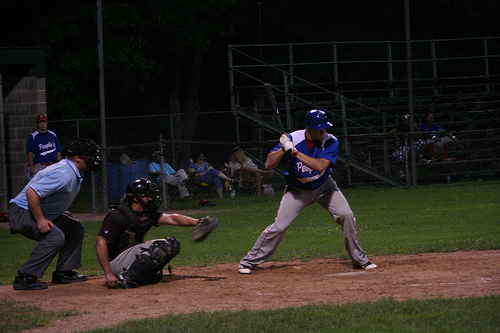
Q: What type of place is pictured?
A: It is a field.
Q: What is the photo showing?
A: It is showing a field.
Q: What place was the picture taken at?
A: It was taken at the field.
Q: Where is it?
A: This is at the field.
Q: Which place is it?
A: It is a field.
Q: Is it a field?
A: Yes, it is a field.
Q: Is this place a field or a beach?
A: It is a field.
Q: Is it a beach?
A: No, it is a field.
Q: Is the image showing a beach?
A: No, the picture is showing a field.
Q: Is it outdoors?
A: Yes, it is outdoors.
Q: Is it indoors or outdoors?
A: It is outdoors.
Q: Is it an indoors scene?
A: No, it is outdoors.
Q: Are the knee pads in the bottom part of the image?
A: Yes, the knee pads are in the bottom of the image.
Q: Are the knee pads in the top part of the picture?
A: No, the knee pads are in the bottom of the image.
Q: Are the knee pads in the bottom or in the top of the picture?
A: The knee pads are in the bottom of the image.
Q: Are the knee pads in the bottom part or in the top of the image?
A: The knee pads are in the bottom of the image.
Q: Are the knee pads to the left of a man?
A: No, the knee pads are to the right of a man.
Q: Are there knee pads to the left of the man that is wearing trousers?
A: Yes, there are knee pads to the left of the man.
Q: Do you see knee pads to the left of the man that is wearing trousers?
A: Yes, there are knee pads to the left of the man.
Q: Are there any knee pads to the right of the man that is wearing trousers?
A: No, the knee pads are to the left of the man.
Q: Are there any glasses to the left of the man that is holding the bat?
A: No, there are knee pads to the left of the man.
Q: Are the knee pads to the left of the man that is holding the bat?
A: Yes, the knee pads are to the left of the man.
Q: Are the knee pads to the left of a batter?
A: No, the knee pads are to the left of the man.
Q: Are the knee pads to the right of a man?
A: No, the knee pads are to the left of a man.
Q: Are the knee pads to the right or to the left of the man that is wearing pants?
A: The knee pads are to the left of the man.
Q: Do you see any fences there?
A: Yes, there is a fence.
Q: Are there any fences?
A: Yes, there is a fence.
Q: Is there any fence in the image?
A: Yes, there is a fence.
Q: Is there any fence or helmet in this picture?
A: Yes, there is a fence.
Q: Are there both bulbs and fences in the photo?
A: No, there is a fence but no light bulbs.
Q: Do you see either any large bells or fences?
A: Yes, there is a large fence.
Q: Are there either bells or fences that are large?
A: Yes, the fence is large.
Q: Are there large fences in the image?
A: Yes, there is a large fence.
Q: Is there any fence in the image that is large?
A: Yes, there is a fence that is large.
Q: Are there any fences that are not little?
A: Yes, there is a large fence.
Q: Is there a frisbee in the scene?
A: No, there are no frisbees.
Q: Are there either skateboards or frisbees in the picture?
A: No, there are no frisbees or skateboards.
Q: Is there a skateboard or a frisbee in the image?
A: No, there are no frisbees or skateboards.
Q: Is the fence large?
A: Yes, the fence is large.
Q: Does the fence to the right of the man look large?
A: Yes, the fence is large.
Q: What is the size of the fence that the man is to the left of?
A: The fence is large.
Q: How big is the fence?
A: The fence is large.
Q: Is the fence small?
A: No, the fence is large.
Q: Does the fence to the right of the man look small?
A: No, the fence is large.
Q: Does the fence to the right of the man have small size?
A: No, the fence is large.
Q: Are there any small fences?
A: No, there is a fence but it is large.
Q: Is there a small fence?
A: No, there is a fence but it is large.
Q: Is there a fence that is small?
A: No, there is a fence but it is large.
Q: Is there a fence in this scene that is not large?
A: No, there is a fence but it is large.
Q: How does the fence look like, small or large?
A: The fence is large.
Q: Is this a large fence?
A: Yes, this is a large fence.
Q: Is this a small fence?
A: No, this is a large fence.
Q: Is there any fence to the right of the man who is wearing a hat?
A: Yes, there is a fence to the right of the man.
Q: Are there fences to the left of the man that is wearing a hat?
A: No, the fence is to the right of the man.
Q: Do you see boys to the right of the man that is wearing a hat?
A: No, there is a fence to the right of the man.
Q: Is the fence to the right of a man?
A: Yes, the fence is to the right of a man.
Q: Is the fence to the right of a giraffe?
A: No, the fence is to the right of a man.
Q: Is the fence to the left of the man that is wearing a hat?
A: No, the fence is to the right of the man.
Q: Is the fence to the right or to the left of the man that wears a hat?
A: The fence is to the right of the man.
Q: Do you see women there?
A: No, there are no women.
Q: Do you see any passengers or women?
A: No, there are no women or passengers.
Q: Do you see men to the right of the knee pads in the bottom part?
A: Yes, there is a man to the right of the knee pads.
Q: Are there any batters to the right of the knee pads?
A: No, there is a man to the right of the knee pads.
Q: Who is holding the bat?
A: The man is holding the bat.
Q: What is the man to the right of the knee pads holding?
A: The man is holding the bat.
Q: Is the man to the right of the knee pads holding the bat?
A: Yes, the man is holding the bat.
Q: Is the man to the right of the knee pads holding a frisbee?
A: No, the man is holding the bat.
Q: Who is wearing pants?
A: The man is wearing pants.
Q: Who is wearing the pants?
A: The man is wearing pants.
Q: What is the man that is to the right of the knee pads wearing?
A: The man is wearing trousers.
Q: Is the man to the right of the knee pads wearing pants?
A: Yes, the man is wearing pants.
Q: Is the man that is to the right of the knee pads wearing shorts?
A: No, the man is wearing pants.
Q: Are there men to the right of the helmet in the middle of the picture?
A: Yes, there is a man to the right of the helmet.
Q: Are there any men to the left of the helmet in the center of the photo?
A: No, the man is to the right of the helmet.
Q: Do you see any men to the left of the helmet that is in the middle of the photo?
A: No, the man is to the right of the helmet.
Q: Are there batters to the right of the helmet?
A: No, there is a man to the right of the helmet.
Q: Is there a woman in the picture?
A: No, there are no women.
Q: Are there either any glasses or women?
A: No, there are no women or glasses.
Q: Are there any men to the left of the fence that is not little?
A: Yes, there is a man to the left of the fence.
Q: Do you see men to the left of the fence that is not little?
A: Yes, there is a man to the left of the fence.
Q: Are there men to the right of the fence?
A: No, the man is to the left of the fence.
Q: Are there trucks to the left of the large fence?
A: No, there is a man to the left of the fence.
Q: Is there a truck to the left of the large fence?
A: No, there is a man to the left of the fence.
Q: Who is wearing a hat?
A: The man is wearing a hat.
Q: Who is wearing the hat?
A: The man is wearing a hat.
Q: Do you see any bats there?
A: Yes, there is a bat.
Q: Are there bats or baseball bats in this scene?
A: Yes, there is a bat.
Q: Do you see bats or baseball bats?
A: Yes, there is a bat.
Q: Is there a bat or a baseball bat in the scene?
A: Yes, there is a bat.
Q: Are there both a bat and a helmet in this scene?
A: Yes, there are both a bat and a helmet.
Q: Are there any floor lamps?
A: No, there are no floor lamps.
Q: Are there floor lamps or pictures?
A: No, there are no floor lamps or pictures.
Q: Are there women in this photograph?
A: No, there are no women.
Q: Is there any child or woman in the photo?
A: No, there are no women or children.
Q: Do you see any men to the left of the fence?
A: Yes, there is a man to the left of the fence.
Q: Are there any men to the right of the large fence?
A: No, the man is to the left of the fence.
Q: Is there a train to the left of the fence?
A: No, there is a man to the left of the fence.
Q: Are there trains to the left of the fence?
A: No, there is a man to the left of the fence.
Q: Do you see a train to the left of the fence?
A: No, there is a man to the left of the fence.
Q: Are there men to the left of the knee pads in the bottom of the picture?
A: Yes, there is a man to the left of the knee pads.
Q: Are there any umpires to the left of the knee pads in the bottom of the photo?
A: No, there is a man to the left of the knee pads.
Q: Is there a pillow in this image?
A: No, there are no pillows.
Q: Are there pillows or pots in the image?
A: No, there are no pillows or pots.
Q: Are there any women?
A: No, there are no women.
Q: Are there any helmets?
A: Yes, there is a helmet.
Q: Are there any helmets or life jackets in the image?
A: Yes, there is a helmet.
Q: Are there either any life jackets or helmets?
A: Yes, there is a helmet.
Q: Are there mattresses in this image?
A: No, there are no mattresses.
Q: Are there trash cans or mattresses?
A: No, there are no mattresses or trash cans.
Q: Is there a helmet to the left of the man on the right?
A: Yes, there is a helmet to the left of the man.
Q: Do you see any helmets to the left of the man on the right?
A: Yes, there is a helmet to the left of the man.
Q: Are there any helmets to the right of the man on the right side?
A: No, the helmet is to the left of the man.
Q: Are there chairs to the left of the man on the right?
A: No, there is a helmet to the left of the man.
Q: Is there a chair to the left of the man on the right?
A: No, there is a helmet to the left of the man.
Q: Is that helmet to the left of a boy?
A: No, the helmet is to the left of the man.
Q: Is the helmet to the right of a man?
A: No, the helmet is to the left of a man.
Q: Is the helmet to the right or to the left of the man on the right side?
A: The helmet is to the left of the man.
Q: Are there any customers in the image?
A: No, there are no customers.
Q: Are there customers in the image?
A: No, there are no customers.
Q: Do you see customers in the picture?
A: No, there are no customers.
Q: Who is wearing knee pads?
A: The man is wearing knee pads.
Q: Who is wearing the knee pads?
A: The man is wearing knee pads.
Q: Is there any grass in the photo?
A: Yes, there is grass.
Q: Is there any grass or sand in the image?
A: Yes, there is grass.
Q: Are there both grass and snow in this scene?
A: No, there is grass but no snow.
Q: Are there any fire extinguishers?
A: No, there are no fire extinguishers.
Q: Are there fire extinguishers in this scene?
A: No, there are no fire extinguishers.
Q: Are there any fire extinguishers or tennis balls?
A: No, there are no fire extinguishers or tennis balls.